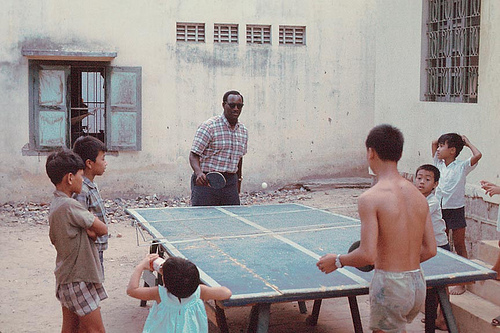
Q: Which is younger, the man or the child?
A: The child is younger than the man.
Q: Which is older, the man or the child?
A: The man is older than the child.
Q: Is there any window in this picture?
A: Yes, there is a window.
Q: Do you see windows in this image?
A: Yes, there is a window.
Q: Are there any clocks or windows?
A: Yes, there is a window.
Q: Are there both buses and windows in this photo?
A: No, there is a window but no buses.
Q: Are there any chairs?
A: No, there are no chairs.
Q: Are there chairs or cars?
A: No, there are no chairs or cars.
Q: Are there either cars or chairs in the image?
A: No, there are no chairs or cars.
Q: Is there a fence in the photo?
A: No, there are no fences.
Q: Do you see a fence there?
A: No, there are no fences.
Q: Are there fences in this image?
A: No, there are no fences.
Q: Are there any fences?
A: No, there are no fences.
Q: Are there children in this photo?
A: Yes, there is a child.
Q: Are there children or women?
A: Yes, there is a child.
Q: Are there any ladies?
A: No, there are no ladies.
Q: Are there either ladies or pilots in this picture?
A: No, there are no ladies or pilots.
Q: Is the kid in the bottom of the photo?
A: Yes, the kid is in the bottom of the image.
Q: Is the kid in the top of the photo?
A: No, the kid is in the bottom of the image.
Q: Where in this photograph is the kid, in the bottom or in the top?
A: The kid is in the bottom of the image.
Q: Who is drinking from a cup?
A: The child is drinking from a cup.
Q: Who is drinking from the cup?
A: The child is drinking from a cup.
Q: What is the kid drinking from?
A: The kid is drinking from a cup.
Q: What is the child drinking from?
A: The kid is drinking from a cup.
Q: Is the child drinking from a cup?
A: Yes, the child is drinking from a cup.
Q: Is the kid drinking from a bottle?
A: No, the kid is drinking from a cup.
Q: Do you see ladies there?
A: No, there are no ladies.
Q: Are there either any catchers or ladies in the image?
A: No, there are no ladies or catchers.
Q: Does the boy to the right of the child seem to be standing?
A: Yes, the boy is standing.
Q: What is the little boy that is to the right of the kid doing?
A: The boy is standing.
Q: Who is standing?
A: The boy is standing.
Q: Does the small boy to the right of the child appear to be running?
A: No, the boy is standing.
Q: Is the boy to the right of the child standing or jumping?
A: The boy is standing.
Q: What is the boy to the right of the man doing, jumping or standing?
A: The boy is standing.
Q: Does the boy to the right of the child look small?
A: Yes, the boy is small.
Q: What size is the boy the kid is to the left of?
A: The boy is small.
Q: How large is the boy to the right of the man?
A: The boy is small.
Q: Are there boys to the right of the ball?
A: Yes, there is a boy to the right of the ball.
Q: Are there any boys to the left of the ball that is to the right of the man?
A: No, the boy is to the right of the ball.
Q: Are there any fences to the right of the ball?
A: No, there is a boy to the right of the ball.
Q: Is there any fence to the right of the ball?
A: No, there is a boy to the right of the ball.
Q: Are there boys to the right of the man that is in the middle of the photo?
A: Yes, there is a boy to the right of the man.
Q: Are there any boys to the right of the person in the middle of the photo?
A: Yes, there is a boy to the right of the man.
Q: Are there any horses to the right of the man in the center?
A: No, there is a boy to the right of the man.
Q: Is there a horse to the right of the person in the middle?
A: No, there is a boy to the right of the man.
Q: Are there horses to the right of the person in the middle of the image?
A: No, there is a boy to the right of the man.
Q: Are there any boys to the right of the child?
A: Yes, there is a boy to the right of the child.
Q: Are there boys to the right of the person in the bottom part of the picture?
A: Yes, there is a boy to the right of the child.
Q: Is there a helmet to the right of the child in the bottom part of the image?
A: No, there is a boy to the right of the kid.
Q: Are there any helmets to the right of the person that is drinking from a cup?
A: No, there is a boy to the right of the kid.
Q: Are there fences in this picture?
A: No, there are no fences.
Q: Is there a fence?
A: No, there are no fences.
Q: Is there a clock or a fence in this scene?
A: No, there are no fences or clocks.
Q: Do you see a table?
A: Yes, there is a table.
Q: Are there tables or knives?
A: Yes, there is a table.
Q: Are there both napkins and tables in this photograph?
A: No, there is a table but no napkins.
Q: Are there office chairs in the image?
A: No, there are no office chairs.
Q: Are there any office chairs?
A: No, there are no office chairs.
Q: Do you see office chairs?
A: No, there are no office chairs.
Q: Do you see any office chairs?
A: No, there are no office chairs.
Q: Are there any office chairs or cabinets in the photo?
A: No, there are no office chairs or cabinets.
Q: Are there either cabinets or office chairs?
A: No, there are no office chairs or cabinets.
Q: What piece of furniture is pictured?
A: The piece of furniture is a table.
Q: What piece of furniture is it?
A: The piece of furniture is a table.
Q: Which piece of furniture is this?
A: This is a table.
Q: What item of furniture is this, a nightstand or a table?
A: This is a table.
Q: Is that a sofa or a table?
A: That is a table.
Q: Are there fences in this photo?
A: No, there are no fences.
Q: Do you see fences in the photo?
A: No, there are no fences.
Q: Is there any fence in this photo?
A: No, there are no fences.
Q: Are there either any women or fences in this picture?
A: No, there are no fences or women.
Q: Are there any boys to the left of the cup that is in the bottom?
A: Yes, there is a boy to the left of the cup.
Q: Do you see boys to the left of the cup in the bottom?
A: Yes, there is a boy to the left of the cup.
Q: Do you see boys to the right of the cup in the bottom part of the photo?
A: No, the boy is to the left of the cup.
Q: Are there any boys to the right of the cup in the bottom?
A: No, the boy is to the left of the cup.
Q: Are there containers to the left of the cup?
A: No, there is a boy to the left of the cup.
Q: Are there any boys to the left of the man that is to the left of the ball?
A: Yes, there is a boy to the left of the man.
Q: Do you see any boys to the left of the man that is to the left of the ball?
A: Yes, there is a boy to the left of the man.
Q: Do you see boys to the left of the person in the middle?
A: Yes, there is a boy to the left of the man.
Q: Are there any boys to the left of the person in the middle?
A: Yes, there is a boy to the left of the man.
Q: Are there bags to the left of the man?
A: No, there is a boy to the left of the man.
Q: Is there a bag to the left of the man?
A: No, there is a boy to the left of the man.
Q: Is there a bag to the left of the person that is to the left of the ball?
A: No, there is a boy to the left of the man.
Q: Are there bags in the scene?
A: No, there are no bags.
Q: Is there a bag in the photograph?
A: No, there are no bags.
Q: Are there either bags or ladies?
A: No, there are no bags or ladies.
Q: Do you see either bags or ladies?
A: No, there are no bags or ladies.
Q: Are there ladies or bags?
A: No, there are no bags or ladies.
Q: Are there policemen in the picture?
A: No, there are no policemen.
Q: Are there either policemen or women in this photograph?
A: No, there are no policemen or women.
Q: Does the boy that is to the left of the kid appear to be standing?
A: Yes, the boy is standing.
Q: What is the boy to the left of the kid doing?
A: The boy is standing.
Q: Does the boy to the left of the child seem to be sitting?
A: No, the boy is standing.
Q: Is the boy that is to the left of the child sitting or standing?
A: The boy is standing.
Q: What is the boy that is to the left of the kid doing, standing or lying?
A: The boy is standing.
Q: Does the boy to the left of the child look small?
A: Yes, the boy is small.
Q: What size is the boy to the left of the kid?
A: The boy is small.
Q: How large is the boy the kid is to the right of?
A: The boy is small.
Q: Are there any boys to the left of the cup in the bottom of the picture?
A: Yes, there is a boy to the left of the cup.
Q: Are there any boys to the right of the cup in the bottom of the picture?
A: No, the boy is to the left of the cup.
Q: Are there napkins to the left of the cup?
A: No, there is a boy to the left of the cup.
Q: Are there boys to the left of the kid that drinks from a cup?
A: Yes, there is a boy to the left of the kid.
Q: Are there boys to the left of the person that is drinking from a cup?
A: Yes, there is a boy to the left of the kid.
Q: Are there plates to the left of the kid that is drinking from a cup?
A: No, there is a boy to the left of the kid.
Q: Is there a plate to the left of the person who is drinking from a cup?
A: No, there is a boy to the left of the kid.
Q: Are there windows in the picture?
A: Yes, there is a window.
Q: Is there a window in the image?
A: Yes, there is a window.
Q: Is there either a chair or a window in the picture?
A: Yes, there is a window.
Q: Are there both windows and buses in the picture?
A: No, there is a window but no buses.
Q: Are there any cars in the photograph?
A: No, there are no cars.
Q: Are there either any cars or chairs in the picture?
A: No, there are no cars or chairs.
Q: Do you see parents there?
A: No, there are no parents.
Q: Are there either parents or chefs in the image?
A: No, there are no parents or chefs.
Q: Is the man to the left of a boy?
A: No, the man is to the right of a boy.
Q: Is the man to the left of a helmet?
A: No, the man is to the left of a boy.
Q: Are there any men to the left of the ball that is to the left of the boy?
A: Yes, there is a man to the left of the ball.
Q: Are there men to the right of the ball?
A: No, the man is to the left of the ball.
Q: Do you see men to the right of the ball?
A: No, the man is to the left of the ball.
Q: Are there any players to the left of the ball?
A: No, there is a man to the left of the ball.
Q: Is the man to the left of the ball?
A: Yes, the man is to the left of the ball.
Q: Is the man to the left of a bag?
A: No, the man is to the left of the ball.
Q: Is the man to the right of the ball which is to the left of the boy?
A: No, the man is to the left of the ball.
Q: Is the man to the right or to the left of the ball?
A: The man is to the left of the ball.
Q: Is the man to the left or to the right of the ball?
A: The man is to the left of the ball.